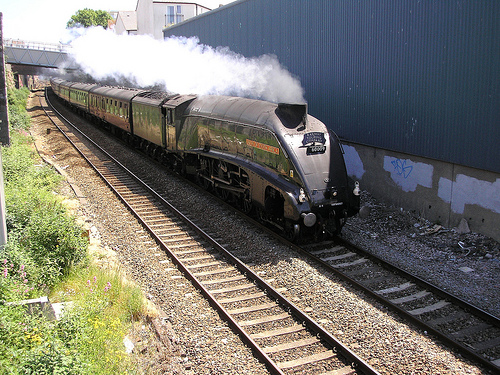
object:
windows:
[52, 77, 136, 135]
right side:
[44, 75, 302, 234]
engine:
[39, 60, 362, 241]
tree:
[67, 6, 110, 31]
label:
[246, 137, 280, 156]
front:
[242, 96, 358, 246]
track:
[41, 85, 500, 375]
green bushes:
[0, 86, 146, 374]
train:
[50, 75, 361, 247]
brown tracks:
[28, 83, 385, 375]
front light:
[299, 180, 362, 203]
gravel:
[31, 89, 500, 375]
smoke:
[67, 22, 319, 114]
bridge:
[2, 38, 72, 68]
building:
[114, 0, 212, 41]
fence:
[162, 3, 497, 173]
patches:
[343, 142, 499, 216]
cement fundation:
[341, 139, 500, 240]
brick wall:
[333, 140, 499, 247]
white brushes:
[395, 162, 430, 191]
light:
[299, 212, 316, 228]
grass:
[0, 83, 151, 375]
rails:
[3, 37, 72, 55]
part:
[373, 276, 459, 333]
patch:
[0, 231, 156, 375]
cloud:
[51, 20, 311, 105]